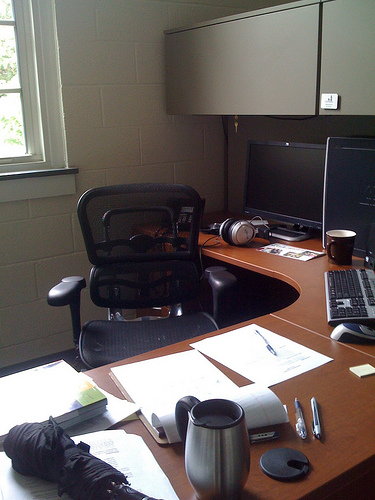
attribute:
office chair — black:
[47, 184, 239, 365]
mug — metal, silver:
[177, 397, 249, 499]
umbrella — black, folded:
[4, 418, 155, 500]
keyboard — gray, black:
[325, 267, 374, 325]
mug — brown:
[324, 228, 358, 266]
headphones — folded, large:
[220, 214, 269, 246]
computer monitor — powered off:
[243, 137, 325, 233]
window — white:
[1, 0, 64, 176]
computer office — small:
[1, 0, 374, 497]